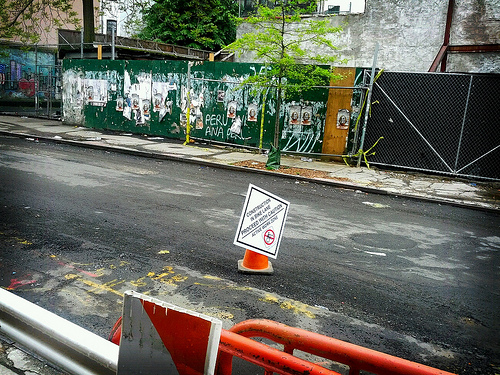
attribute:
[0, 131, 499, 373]
road — Part, large grey cement , cement , large cement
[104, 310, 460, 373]
railing — orange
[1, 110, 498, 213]
sidewalk — old patched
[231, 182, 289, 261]
sign — white, small, black, white and red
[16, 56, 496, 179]
fence — chain link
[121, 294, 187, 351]
sign — construction caution, drivers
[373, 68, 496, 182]
fence — chain link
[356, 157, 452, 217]
sidewalk — middle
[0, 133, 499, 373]
cement road — Part , cement 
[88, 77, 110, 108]
poster — various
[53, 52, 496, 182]
fence — construction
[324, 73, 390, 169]
tape — yellow, caution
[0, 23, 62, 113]
graffiti — art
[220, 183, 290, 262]
sign — black, white, red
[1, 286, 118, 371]
railing — metal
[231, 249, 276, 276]
cone — traffic, orange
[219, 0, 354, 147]
brtree — green 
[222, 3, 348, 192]
tree — healthy 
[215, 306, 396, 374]
rails — orange guard, construction project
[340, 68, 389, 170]
tape — yellow caution construction zone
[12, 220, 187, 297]
marking — yellow 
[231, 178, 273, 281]
traffic cone — orange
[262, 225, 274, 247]
posting — no bike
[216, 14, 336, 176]
folage — bright green